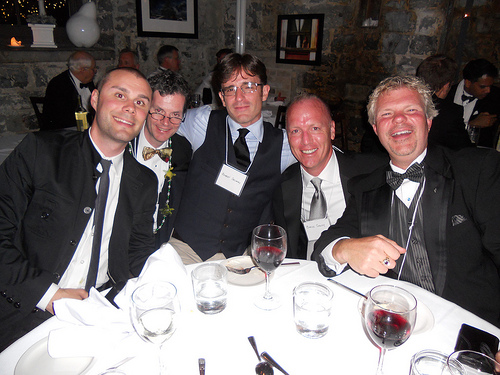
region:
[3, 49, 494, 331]
five guys posing for a photo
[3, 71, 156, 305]
a guy with a black tie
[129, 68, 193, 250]
a guy with glasses and a gold bowtie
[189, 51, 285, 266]
a man wearing a tie and a vest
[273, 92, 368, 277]
a man with a gray tie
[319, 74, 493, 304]
a blonde man with a striped bowtie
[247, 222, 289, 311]
a glass of wine that is half full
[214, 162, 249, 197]
name tag the man in the center is wearing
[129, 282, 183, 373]
an empty wine glass on the table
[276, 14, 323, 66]
a photo on the wall behind the men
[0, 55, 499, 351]
People looking at camera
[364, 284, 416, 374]
A glass of wine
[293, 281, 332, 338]
A cup of water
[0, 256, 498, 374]
The table is round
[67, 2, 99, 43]
A bulbous white object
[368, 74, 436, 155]
The man is smiling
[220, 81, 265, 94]
The man has glasses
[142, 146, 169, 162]
The tie is yellow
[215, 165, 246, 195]
The tag is white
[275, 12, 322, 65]
Picture on the wall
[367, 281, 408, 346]
The wine is red.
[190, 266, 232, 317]
The liquid inside the glass is clear.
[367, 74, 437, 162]
The man's hair is blonde.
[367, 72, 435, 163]
The man's hair is short.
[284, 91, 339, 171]
The man is balding.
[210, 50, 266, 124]
The man is wearing glasses.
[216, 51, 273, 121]
The man's hair is brown.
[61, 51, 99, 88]
The man's hair is white.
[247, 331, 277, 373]
The spoon is silver.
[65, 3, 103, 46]
The vase in the background is white.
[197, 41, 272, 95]
man has dark brown hair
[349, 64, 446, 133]
man has blonde hair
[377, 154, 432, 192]
man wearing bow tie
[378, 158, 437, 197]
bow tie is black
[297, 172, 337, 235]
wearing grey dress tie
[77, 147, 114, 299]
man wearing skinny tie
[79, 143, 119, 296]
skinny tie is black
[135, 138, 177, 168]
man wearing multicolored bow tie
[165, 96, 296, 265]
man wearing black vest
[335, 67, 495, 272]
man wearing a tie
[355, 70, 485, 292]
man wearing a suit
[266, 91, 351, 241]
man wearing a tie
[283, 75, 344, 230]
man wearing a suit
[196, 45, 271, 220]
man wearing a tie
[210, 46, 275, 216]
man wearing a vest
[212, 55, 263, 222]
man wearing a badge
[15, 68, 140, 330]
man wearing a tie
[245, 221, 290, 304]
glass of wine on a table